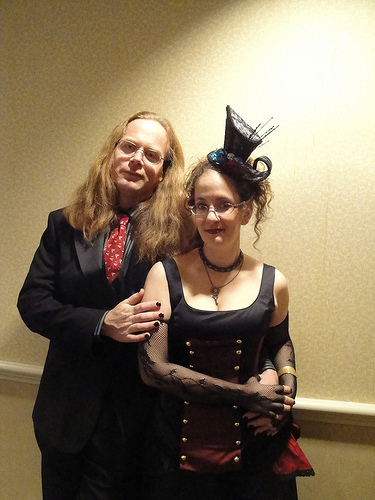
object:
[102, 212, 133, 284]
tie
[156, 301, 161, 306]
nails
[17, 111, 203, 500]
man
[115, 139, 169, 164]
glasses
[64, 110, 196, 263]
hair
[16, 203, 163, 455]
jacket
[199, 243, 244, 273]
choker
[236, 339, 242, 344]
button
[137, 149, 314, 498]
woman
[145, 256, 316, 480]
top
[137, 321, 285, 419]
gloves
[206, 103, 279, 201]
hat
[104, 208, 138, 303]
shirt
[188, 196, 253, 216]
glasses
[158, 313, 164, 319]
fingernails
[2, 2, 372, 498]
wall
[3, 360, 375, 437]
moulding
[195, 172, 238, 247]
face